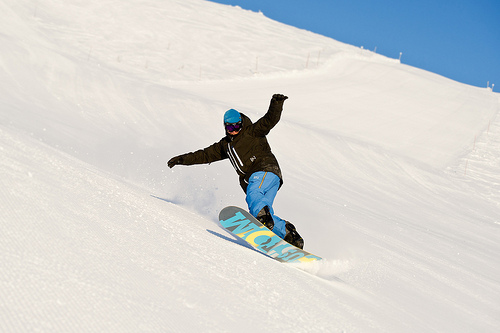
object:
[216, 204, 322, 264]
snowboard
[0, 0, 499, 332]
slope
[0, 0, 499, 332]
snow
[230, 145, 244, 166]
stripes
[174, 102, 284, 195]
coat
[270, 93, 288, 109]
glove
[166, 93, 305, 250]
person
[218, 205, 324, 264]
ski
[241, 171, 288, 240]
pants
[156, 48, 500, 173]
wide path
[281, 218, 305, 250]
boot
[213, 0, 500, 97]
sky